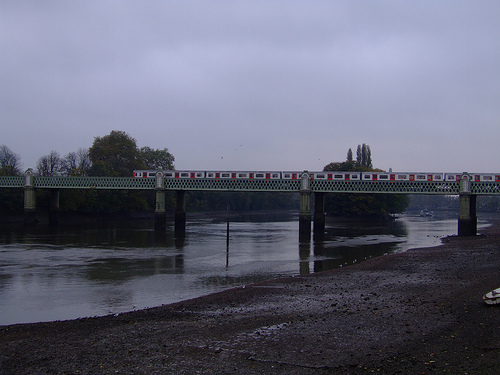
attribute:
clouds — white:
[1, 0, 499, 173]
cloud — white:
[161, 33, 445, 75]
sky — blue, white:
[363, 61, 488, 115]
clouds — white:
[198, 34, 302, 109]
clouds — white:
[163, 3, 288, 102]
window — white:
[177, 167, 192, 181]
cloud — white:
[158, 14, 359, 122]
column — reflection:
[258, 199, 335, 261]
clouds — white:
[191, 37, 333, 97]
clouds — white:
[169, 26, 426, 159]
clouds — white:
[124, 29, 360, 109]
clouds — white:
[147, 20, 497, 101]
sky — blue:
[7, 5, 499, 122]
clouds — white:
[138, 37, 416, 96]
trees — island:
[274, 130, 424, 257]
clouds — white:
[103, 59, 429, 122]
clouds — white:
[127, 37, 438, 97]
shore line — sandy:
[5, 211, 482, 231]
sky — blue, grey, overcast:
[0, 1, 498, 174]